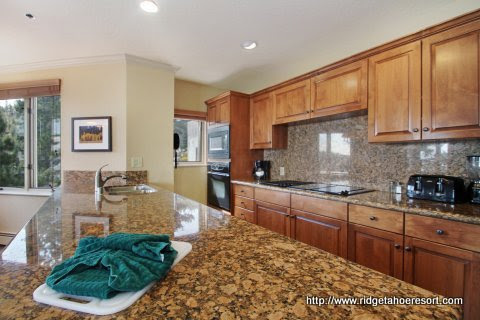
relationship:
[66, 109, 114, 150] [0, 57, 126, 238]
picture on wall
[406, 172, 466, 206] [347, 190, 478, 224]
toaster on counter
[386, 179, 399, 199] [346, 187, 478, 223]
shaker on counter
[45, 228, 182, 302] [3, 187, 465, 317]
towel on table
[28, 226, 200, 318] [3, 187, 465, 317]
board on table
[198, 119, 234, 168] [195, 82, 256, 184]
microwave in cabinet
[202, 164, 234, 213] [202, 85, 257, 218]
oven in cabinet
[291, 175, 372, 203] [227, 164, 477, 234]
stove top on counter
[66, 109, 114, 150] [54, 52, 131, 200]
picture hanging on wall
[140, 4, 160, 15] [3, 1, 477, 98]
light in ceiling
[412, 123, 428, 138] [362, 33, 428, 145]
knobs on cabinet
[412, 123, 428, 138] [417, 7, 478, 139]
knobs on cabinet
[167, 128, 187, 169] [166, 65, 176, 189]
phone hanging on wall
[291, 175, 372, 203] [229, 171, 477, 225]
stove top on counter top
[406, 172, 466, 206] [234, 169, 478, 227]
toaster sitting on counter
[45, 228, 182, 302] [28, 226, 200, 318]
towel sitting on board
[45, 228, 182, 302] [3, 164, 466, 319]
towel on table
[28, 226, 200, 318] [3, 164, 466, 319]
board on table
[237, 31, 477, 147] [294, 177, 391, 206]
cabinets over sink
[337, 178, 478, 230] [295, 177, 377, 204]
counter near sink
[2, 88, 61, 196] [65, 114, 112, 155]
windows next to picture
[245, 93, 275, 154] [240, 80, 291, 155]
door on cabinet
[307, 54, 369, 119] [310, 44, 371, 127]
door on cabinet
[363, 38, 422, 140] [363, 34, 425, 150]
door on cabinet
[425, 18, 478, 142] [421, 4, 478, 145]
door on cabinet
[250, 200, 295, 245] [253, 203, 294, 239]
door on cabinet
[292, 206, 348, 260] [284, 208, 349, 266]
door on cabinet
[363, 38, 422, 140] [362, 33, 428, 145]
door on cabinet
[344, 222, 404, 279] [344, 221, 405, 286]
door on cabinet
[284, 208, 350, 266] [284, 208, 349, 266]
door on cabinet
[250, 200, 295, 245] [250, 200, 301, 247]
door on cabinet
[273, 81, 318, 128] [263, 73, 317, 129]
door on cabinet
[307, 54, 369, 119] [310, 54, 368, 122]
door on cabinet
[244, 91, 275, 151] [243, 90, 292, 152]
door on cabinet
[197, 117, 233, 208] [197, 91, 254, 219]
stove built into wall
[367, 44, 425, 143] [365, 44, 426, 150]
door on cabinet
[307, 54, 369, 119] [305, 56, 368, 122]
door on cabinet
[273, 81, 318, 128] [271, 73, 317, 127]
door on cabinet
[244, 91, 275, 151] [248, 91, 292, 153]
door on cabinet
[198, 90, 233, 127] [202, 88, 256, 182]
door on cabinet